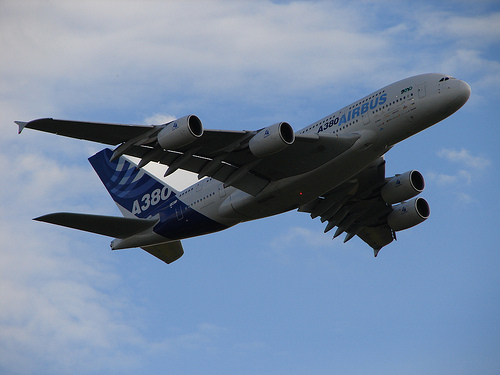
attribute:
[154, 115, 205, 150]
engine — part 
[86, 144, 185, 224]
tail — white, blue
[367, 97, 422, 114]
windows — passenger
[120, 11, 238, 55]
clouds — puffy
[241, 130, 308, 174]
engine — white, blue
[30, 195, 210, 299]
tail — blue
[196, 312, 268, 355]
cloud — edge 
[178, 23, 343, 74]
clouds — white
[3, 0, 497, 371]
sky — white, blue, part 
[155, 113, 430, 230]
engines — blue, white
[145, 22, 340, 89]
clouds — white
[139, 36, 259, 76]
clouds — white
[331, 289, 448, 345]
sky — blue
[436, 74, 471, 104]
nose — white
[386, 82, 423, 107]
window — small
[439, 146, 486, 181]
clouds — white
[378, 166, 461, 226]
engine — large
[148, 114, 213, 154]
engine — large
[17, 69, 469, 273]
airliner — white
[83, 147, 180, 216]
tail — white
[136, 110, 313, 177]
engine — large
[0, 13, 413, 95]
sky — blue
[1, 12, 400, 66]
clouds — white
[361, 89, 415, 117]
row — long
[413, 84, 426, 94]
window — small